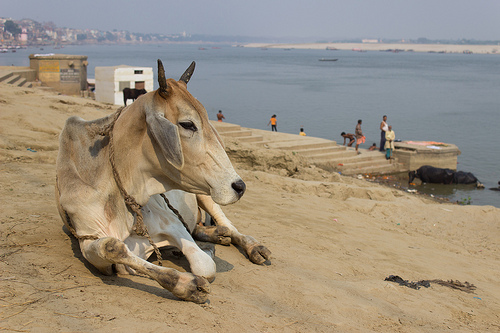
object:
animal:
[52, 58, 275, 303]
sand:
[0, 59, 500, 333]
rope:
[52, 104, 211, 278]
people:
[298, 128, 306, 136]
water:
[0, 31, 500, 205]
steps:
[348, 163, 398, 174]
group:
[26, 52, 156, 106]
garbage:
[360, 173, 403, 190]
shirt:
[270, 118, 277, 125]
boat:
[317, 57, 338, 61]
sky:
[0, 1, 500, 40]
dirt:
[281, 204, 380, 256]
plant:
[383, 274, 480, 294]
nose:
[231, 180, 246, 197]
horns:
[178, 61, 198, 83]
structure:
[94, 64, 154, 106]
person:
[354, 119, 367, 154]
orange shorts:
[356, 136, 366, 144]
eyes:
[178, 120, 197, 131]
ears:
[155, 58, 171, 98]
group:
[340, 115, 397, 160]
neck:
[105, 107, 149, 215]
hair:
[384, 115, 387, 117]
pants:
[271, 125, 277, 132]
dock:
[217, 121, 463, 176]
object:
[234, 35, 497, 59]